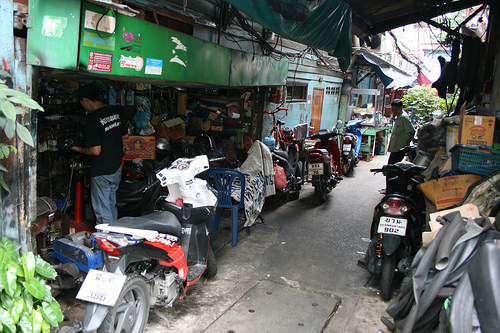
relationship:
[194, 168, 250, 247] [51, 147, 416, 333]
blue chair on cement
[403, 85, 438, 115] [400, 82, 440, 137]
green leaves on tree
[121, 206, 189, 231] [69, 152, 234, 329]
seat on a scooter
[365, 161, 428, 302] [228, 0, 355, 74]
motorcycle parked under green tarp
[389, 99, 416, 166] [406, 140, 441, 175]
man leaning on table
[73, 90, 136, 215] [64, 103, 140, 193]
man wearing a shirt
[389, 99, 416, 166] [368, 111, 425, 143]
man standing shirt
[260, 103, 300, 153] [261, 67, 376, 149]
bicycle laying against wall